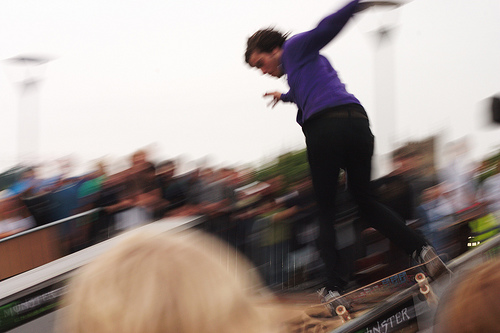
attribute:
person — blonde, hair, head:
[51, 226, 287, 333]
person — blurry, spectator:
[103, 150, 160, 210]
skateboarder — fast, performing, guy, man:
[241, 1, 431, 297]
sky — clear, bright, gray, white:
[3, 0, 498, 174]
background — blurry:
[1, 149, 308, 234]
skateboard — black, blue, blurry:
[307, 252, 449, 312]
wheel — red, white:
[335, 303, 347, 317]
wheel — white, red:
[415, 270, 428, 282]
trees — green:
[254, 149, 308, 182]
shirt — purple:
[274, 0, 359, 119]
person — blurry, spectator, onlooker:
[9, 165, 61, 191]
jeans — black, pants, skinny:
[301, 109, 424, 291]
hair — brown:
[245, 28, 288, 60]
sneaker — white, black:
[315, 286, 350, 316]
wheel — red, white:
[419, 284, 430, 295]